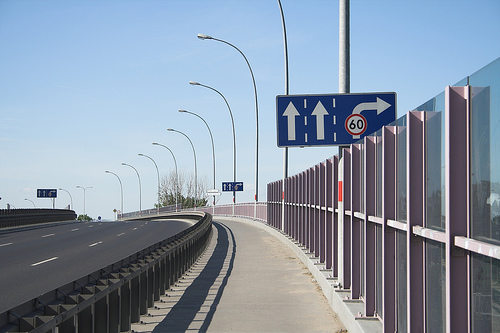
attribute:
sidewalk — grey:
[121, 194, 329, 331]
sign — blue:
[272, 92, 395, 147]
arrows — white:
[269, 82, 419, 147]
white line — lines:
[89, 238, 104, 248]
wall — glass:
[265, 59, 497, 331]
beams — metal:
[442, 85, 471, 331]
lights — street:
[45, 0, 449, 212]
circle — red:
[336, 108, 385, 133]